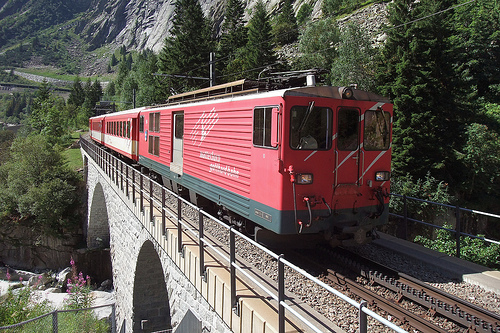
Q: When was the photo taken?
A: During the day.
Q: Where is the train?
A: Crossing a tressel.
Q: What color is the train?
A: Red.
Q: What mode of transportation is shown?
A: Railroad.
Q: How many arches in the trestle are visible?
A: Two.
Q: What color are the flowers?
A: Purple.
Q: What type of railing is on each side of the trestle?
A: Metal.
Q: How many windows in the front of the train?
A: Three.